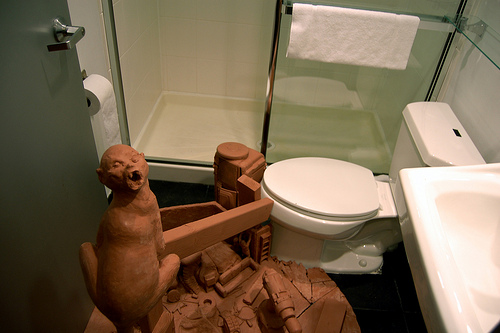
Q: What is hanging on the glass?
A: A towel.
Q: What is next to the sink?
A: A toilet.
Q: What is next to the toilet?
A: A sink.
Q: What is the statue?
A: A monkey.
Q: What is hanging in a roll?
A: Toilet paper.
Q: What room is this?
A: A bathroom.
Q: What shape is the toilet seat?
A: Oval.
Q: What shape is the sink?
A: Rectangular.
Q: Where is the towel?
A: On a hanger.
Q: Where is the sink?
A: By the toilet.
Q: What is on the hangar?
A: A towel.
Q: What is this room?
A: A bathroom.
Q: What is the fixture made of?
A: Clay.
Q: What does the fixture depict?
A: A monkey.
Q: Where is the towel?
A: On the rack.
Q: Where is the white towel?
A: On shower door.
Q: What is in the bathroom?
A: A bizarre clay figurine.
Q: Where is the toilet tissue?
A: On a fixture on the wall.